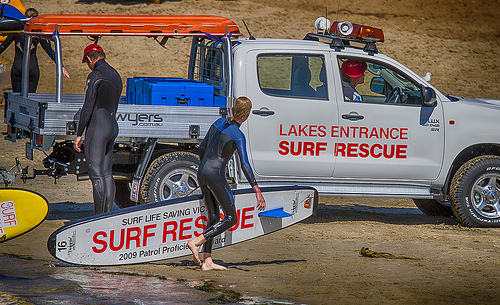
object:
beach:
[0, 0, 500, 305]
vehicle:
[3, 0, 499, 228]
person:
[187, 96, 267, 272]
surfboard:
[0, 186, 51, 243]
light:
[327, 21, 385, 43]